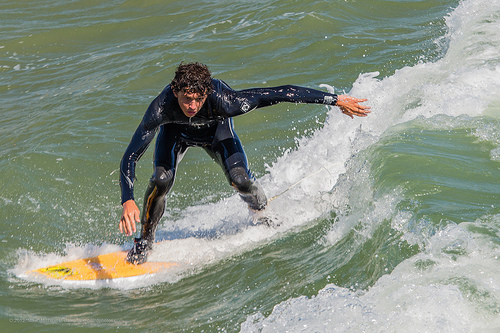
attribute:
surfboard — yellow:
[27, 246, 202, 281]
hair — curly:
[165, 60, 220, 99]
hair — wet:
[167, 58, 219, 97]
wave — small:
[340, 43, 485, 305]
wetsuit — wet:
[128, 100, 258, 177]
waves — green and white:
[259, 87, 498, 324]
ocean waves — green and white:
[3, 4, 495, 329]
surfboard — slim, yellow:
[33, 216, 285, 289]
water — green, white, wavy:
[3, 4, 497, 326]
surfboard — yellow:
[23, 189, 331, 291]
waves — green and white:
[288, 56, 496, 326]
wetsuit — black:
[93, 60, 321, 267]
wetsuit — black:
[87, 73, 319, 283]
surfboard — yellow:
[41, 215, 230, 330]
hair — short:
[169, 60, 219, 98]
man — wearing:
[90, 59, 372, 250]